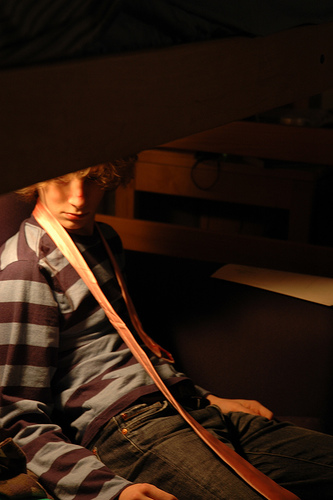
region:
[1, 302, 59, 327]
black stripe on shirt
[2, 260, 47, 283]
black stripe on shirt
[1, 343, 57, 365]
black stripe on shirt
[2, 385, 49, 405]
black stripe on shirt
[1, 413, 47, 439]
black stripe on shirt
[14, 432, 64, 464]
black stripe on shirt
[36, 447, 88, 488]
black stripe on shirt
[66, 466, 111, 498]
black stripe on shirt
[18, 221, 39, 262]
black stripe on shirt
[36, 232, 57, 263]
black stripe on shirt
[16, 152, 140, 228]
a man with curly blonde hair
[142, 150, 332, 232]
a wooden desk behind the person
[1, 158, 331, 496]
a boy wearing a striped shirt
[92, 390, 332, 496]
the jeans of the man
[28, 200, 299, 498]
the pink tie around the boys neck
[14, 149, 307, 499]
a young man with a tie around his neck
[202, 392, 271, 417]
the hand of the boy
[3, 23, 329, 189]
a wood plank hanging above the man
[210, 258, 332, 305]
a white paper next to the boy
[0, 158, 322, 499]
a man sitting down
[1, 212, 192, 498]
the shirt is stripes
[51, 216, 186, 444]
the tie is brown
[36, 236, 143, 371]
the tie is brown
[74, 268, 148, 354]
the tie is brown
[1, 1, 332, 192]
Mattress over a boy's head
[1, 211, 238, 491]
Boy wearing a long sleeve black and blue striped shirt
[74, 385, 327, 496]
Boy wearing blue jeans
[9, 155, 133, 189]
Curly hair on a boy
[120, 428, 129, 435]
Metal clasp on jeans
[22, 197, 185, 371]
Tie around a boy's neck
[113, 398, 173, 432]
Front pocket on blue jeans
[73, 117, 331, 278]
Wooden shelf behind a boy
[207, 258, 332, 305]
White paper on a bed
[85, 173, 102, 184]
Boy's eye looking down